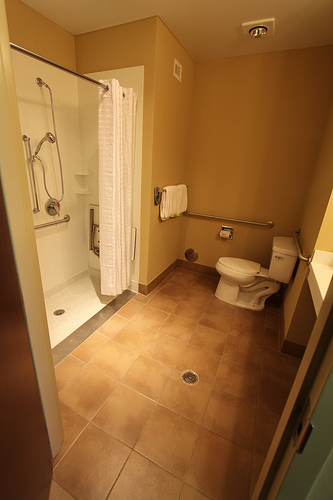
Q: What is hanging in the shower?
A: A white curtain.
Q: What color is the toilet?
A: White.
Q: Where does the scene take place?
A: In a bathroom.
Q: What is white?
A: Towels.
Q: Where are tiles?
A: On the floor.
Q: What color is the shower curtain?
A: White.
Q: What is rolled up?
A: Toilet paper.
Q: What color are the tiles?
A: Beige.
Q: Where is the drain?
A: On the floor.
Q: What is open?
A: The shower curtain.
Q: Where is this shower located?
A: In the bathroom.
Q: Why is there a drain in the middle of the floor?
A: Because the shower doesn't have a ledge.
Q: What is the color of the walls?
A: Gold.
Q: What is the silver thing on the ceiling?
A: A fan.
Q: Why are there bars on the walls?
A: For handicapped people.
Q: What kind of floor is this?
A: Tile.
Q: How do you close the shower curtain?
A: You slide it.